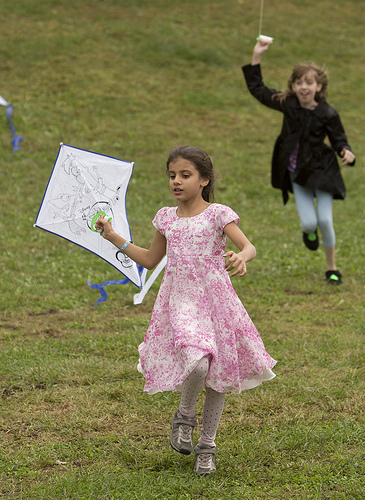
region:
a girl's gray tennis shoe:
[166, 409, 197, 453]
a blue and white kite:
[30, 138, 147, 302]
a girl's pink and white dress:
[132, 200, 278, 400]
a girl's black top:
[242, 57, 357, 205]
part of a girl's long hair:
[164, 146, 222, 202]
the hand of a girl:
[222, 246, 251, 278]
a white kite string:
[255, 0, 269, 35]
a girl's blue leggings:
[286, 183, 338, 250]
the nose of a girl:
[172, 171, 182, 185]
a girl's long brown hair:
[271, 64, 335, 111]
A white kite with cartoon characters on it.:
[29, 128, 157, 313]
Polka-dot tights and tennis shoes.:
[147, 344, 265, 461]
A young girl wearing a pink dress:
[101, 129, 292, 403]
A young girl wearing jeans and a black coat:
[233, 22, 362, 239]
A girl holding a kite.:
[38, 142, 299, 283]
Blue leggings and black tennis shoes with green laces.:
[259, 176, 362, 282]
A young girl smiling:
[272, 56, 335, 110]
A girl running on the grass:
[227, 28, 362, 300]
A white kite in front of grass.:
[12, 45, 156, 298]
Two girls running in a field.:
[8, 33, 357, 335]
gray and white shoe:
[171, 407, 191, 450]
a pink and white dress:
[135, 201, 272, 395]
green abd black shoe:
[324, 268, 337, 280]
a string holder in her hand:
[256, 31, 269, 47]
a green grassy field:
[21, 0, 197, 99]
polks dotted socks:
[177, 362, 204, 410]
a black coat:
[238, 63, 350, 188]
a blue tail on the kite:
[94, 272, 141, 309]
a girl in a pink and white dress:
[147, 145, 265, 477]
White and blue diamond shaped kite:
[27, 140, 143, 286]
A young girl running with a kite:
[29, 139, 278, 477]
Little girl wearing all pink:
[95, 145, 277, 476]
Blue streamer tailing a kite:
[94, 256, 143, 313]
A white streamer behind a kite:
[134, 262, 165, 301]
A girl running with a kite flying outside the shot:
[243, 0, 363, 286]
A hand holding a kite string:
[246, 0, 276, 59]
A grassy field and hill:
[1, 2, 363, 498]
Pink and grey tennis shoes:
[168, 410, 222, 477]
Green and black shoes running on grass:
[302, 228, 342, 286]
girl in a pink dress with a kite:
[32, 141, 279, 483]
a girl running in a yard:
[242, 24, 362, 294]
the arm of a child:
[237, 30, 287, 114]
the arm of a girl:
[215, 207, 256, 276]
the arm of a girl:
[93, 210, 163, 270]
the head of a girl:
[159, 145, 214, 207]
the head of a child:
[284, 56, 335, 109]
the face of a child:
[289, 72, 319, 100]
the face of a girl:
[164, 156, 197, 200]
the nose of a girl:
[169, 173, 186, 188]